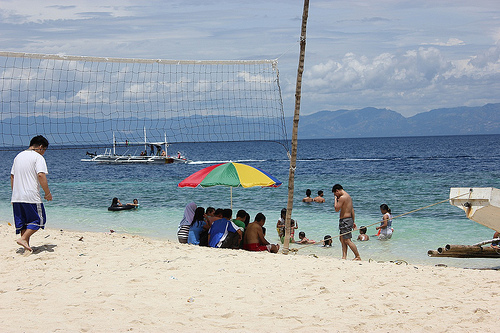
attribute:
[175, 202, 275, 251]
people — sitting, enjoying, huddled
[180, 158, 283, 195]
umbrella — colored, multicolored, multi-colored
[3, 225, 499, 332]
sand — beige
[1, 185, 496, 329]
beach — sandy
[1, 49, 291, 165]
net — extended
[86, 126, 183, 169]
boat — recreational, white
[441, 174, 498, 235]
boat — tied, parked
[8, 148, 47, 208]
top — white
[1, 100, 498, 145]
mountains — distant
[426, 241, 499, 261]
pipes — metal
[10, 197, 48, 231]
shorts — blue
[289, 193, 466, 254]
rope — attached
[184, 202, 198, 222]
towel — white